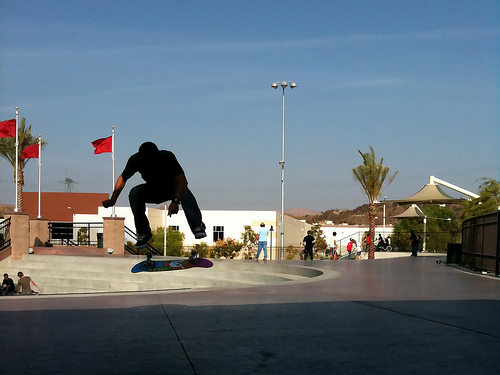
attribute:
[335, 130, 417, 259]
palm tree — green, brown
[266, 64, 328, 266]
light pole — tall, silver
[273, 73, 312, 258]
lamp — tall, street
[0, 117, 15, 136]
flag — red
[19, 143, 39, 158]
flag — red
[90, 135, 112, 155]
flag — red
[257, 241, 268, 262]
jeans — blue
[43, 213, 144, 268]
fence — brown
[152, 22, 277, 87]
sky — daytime, blue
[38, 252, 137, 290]
stairs — concrete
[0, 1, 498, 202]
sky — blue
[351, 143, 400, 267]
tree — warm weather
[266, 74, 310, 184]
lights — outdoor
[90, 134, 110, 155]
flag — nondescript, red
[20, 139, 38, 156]
flag — red, nondescript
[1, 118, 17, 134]
flag — red, nondescript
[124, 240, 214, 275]
skateboard — flipped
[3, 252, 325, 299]
concrete stairs — oval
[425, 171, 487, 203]
pole — white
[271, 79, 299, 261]
lamp — high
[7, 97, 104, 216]
flag — red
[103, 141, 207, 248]
man — jumping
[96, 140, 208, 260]
man — jumping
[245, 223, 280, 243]
shirt — light blue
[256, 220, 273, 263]
man — walking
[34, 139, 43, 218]
flagpole — white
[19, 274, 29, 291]
shirt — brown